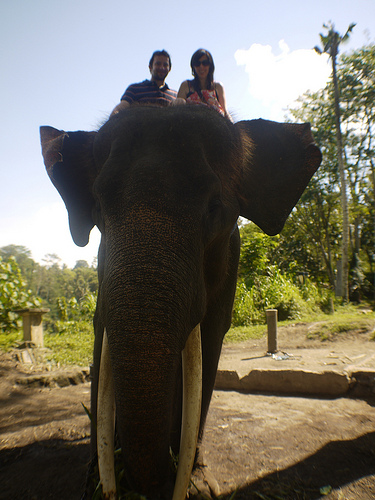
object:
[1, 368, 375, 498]
concrete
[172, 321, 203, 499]
tusk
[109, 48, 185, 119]
man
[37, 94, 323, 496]
elephant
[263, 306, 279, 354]
pole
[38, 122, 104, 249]
ear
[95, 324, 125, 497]
tusks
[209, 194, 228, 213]
eye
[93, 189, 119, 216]
eye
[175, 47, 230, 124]
person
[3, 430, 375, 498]
shadow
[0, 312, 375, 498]
ground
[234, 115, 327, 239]
ear